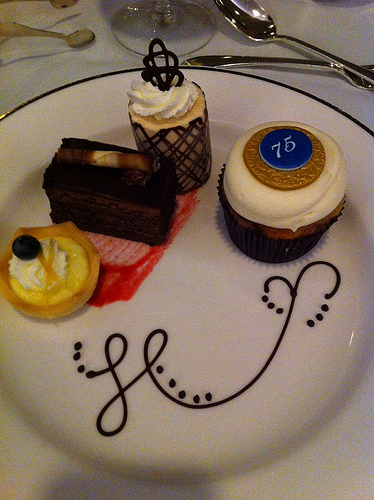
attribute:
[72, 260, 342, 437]
design — fancy, decorative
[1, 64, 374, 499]
plate — full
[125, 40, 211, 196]
pastry — white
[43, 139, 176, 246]
cake — riche, chocolate, mousse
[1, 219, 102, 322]
tart — lemon, dessert, small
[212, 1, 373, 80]
spoon — silver, small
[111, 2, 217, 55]
base — clear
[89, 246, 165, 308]
syrup — smeared, red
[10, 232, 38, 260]
blueberry — fresh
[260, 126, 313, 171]
circle — blue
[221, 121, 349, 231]
frosting — vanilla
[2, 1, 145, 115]
tablecloth — white